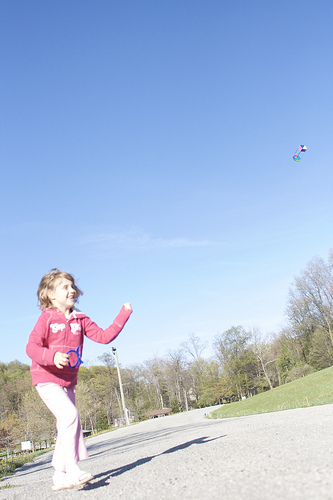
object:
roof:
[148, 409, 170, 417]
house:
[145, 407, 172, 420]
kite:
[292, 145, 308, 161]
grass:
[211, 362, 331, 419]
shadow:
[85, 433, 226, 487]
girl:
[24, 268, 135, 493]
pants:
[33, 384, 92, 470]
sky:
[1, 1, 80, 75]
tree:
[287, 253, 332, 363]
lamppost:
[111, 343, 132, 427]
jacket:
[25, 307, 134, 386]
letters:
[48, 321, 82, 335]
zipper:
[61, 317, 71, 344]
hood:
[70, 309, 92, 321]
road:
[0, 412, 333, 498]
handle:
[66, 345, 84, 370]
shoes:
[49, 468, 94, 492]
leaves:
[229, 353, 253, 372]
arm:
[83, 301, 138, 346]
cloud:
[98, 230, 226, 257]